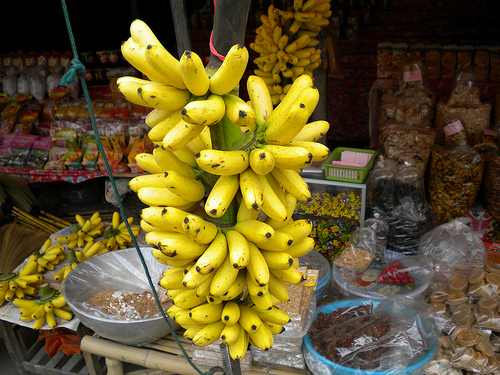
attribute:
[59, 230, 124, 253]
bananas — hanging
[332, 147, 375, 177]
mailbox — small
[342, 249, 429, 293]
wrappings — plastic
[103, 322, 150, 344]
bowl — silver, blue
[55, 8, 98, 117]
rope — green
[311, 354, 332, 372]
bowl — blue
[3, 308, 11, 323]
table — wooden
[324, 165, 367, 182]
basket — green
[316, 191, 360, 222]
flowers — yellow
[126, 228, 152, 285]
cording — blue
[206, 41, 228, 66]
rope — red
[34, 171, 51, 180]
fabric — red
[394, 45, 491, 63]
food items — dried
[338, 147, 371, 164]
box — green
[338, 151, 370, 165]
papers — pink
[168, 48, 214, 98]
banana — ripe, yellow